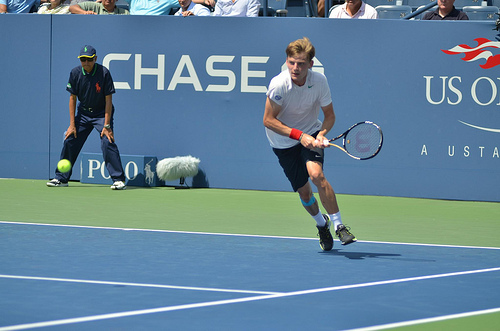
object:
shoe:
[332, 223, 360, 246]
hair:
[283, 37, 315, 60]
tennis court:
[0, 219, 500, 329]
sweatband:
[287, 128, 302, 140]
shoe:
[315, 220, 334, 252]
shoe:
[110, 180, 125, 191]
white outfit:
[261, 74, 340, 145]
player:
[259, 38, 356, 258]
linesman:
[48, 45, 126, 192]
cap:
[75, 44, 98, 59]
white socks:
[327, 215, 346, 230]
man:
[261, 38, 370, 256]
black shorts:
[271, 141, 326, 191]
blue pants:
[59, 116, 120, 180]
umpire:
[47, 46, 128, 189]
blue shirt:
[64, 66, 113, 119]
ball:
[55, 156, 72, 174]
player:
[50, 50, 116, 187]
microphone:
[157, 155, 197, 179]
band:
[286, 127, 304, 144]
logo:
[101, 51, 270, 98]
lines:
[0, 265, 277, 298]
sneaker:
[332, 227, 360, 246]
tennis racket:
[310, 118, 385, 162]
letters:
[239, 51, 271, 93]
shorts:
[271, 139, 332, 193]